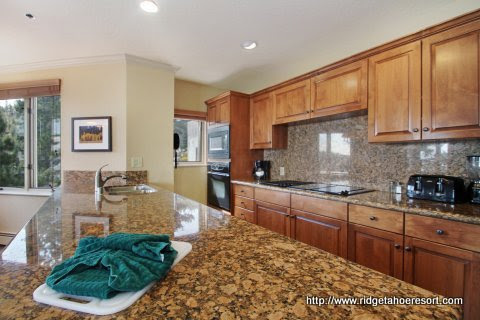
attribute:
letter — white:
[305, 292, 311, 305]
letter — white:
[317, 295, 325, 307]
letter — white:
[331, 295, 343, 307]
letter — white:
[339, 294, 350, 305]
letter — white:
[348, 290, 357, 304]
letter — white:
[453, 296, 462, 304]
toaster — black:
[406, 172, 466, 206]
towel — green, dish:
[45, 228, 182, 302]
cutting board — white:
[31, 235, 194, 314]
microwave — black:
[198, 119, 234, 168]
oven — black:
[202, 164, 234, 213]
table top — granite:
[4, 161, 462, 318]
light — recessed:
[140, 4, 160, 15]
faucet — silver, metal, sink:
[85, 157, 144, 198]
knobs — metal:
[412, 123, 428, 138]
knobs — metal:
[418, 122, 431, 135]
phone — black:
[167, 128, 187, 169]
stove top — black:
[291, 175, 372, 203]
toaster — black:
[397, 170, 466, 205]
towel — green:
[40, 225, 176, 298]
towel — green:
[35, 221, 184, 304]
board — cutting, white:
[28, 226, 200, 318]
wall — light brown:
[1, 54, 179, 192]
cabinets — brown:
[237, 31, 477, 147]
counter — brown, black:
[337, 178, 478, 230]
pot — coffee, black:
[252, 164, 267, 180]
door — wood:
[245, 93, 275, 154]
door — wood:
[307, 54, 369, 119]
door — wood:
[363, 38, 422, 140]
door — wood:
[425, 18, 478, 142]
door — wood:
[253, 206, 288, 244]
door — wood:
[292, 206, 348, 260]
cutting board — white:
[22, 230, 195, 312]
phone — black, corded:
[169, 128, 182, 169]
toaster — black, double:
[402, 164, 471, 212]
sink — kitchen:
[91, 164, 156, 202]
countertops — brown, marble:
[1, 183, 456, 319]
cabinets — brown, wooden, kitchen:
[201, 5, 478, 319]